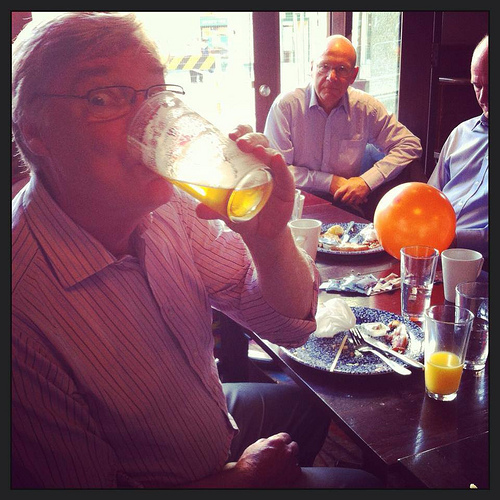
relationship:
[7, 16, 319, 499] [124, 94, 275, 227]
man has glass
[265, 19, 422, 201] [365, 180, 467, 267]
person above ball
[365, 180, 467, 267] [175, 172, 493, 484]
ball on table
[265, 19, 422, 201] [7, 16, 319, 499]
person near man